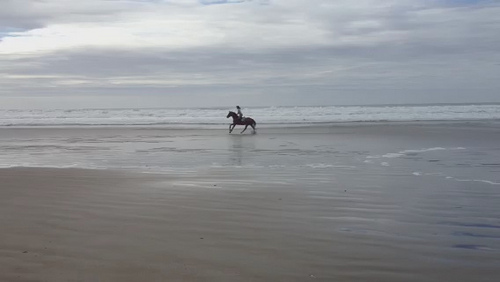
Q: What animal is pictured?
A: Horse.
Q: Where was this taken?
A: Beach.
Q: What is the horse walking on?
A: Sand.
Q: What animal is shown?
A: Horse.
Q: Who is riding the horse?
A: A person.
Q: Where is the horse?
A: On the beach.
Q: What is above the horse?
A: A sky.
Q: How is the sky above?
A: Cloudy.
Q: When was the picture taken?
A: Daytime.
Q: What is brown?
A: Sand.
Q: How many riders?
A: One.